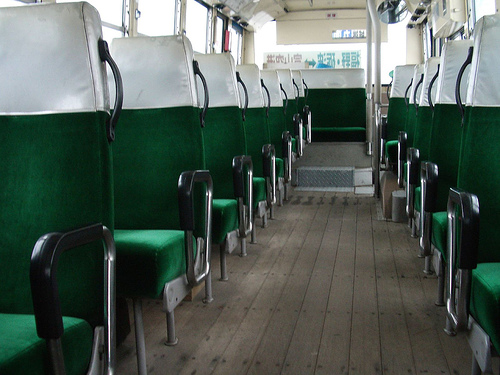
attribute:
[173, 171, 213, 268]
arms — metal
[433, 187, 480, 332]
arms — metal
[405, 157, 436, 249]
arms — metal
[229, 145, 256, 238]
arms — metal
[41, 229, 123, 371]
arms — metal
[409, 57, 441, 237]
seat — green, white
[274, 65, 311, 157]
seat — white, green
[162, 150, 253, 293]
rest — arm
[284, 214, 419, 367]
hardwood floors — raw, tan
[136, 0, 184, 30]
window — side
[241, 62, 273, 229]
seat — white, green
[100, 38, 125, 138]
handle — plastic, black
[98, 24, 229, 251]
white seat — green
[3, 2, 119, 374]
seating — green, white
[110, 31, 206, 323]
seating — green, white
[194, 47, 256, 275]
seating — green, white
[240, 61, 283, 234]
seating — green, white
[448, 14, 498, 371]
seating — green, white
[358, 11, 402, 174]
pole — metal, tall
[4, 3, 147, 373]
seat — white, green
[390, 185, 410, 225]
canister — metal, round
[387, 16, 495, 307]
seat — white, green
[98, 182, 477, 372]
floor — hardwood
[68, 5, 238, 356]
seat — top, white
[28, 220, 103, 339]
arm rest — metal, black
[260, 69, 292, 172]
seat — green, white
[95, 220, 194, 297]
seat — white, green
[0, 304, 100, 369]
seat — white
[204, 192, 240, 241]
seat — white, green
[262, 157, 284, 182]
seat — white, green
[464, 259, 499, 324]
seat — white, green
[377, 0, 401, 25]
mirror — round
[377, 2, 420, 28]
mirror — driver's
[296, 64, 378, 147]
back seat — green, white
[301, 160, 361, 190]
grate — white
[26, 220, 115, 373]
arm rest — black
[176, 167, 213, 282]
arm rest — black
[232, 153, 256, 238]
arm rest — black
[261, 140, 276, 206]
arm rest — black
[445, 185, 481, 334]
arm rest — black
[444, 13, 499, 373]
chair — white, green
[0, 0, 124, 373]
chair — white, green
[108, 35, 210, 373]
chair — white, green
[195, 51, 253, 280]
chair — white, green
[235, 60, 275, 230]
chair — white, green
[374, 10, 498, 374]
seats — white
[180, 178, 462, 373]
floor plank — wooden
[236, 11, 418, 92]
windshield — glass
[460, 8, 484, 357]
seat — green, white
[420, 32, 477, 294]
seat — green, white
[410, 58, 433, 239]
seat — white, green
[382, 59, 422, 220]
seat — white, green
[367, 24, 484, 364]
row — white, green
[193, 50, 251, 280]
seat — green, white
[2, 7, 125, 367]
bus seat — green, white